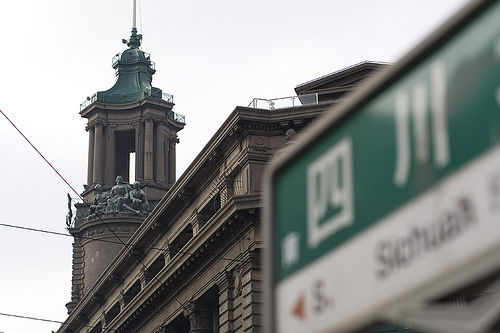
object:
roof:
[77, 0, 177, 112]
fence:
[243, 91, 323, 110]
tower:
[66, 0, 186, 317]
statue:
[120, 27, 143, 47]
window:
[89, 319, 101, 330]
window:
[123, 278, 143, 310]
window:
[145, 250, 165, 282]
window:
[168, 222, 194, 264]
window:
[113, 127, 140, 184]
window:
[189, 285, 225, 330]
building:
[55, 0, 500, 333]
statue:
[84, 172, 155, 218]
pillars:
[91, 126, 107, 182]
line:
[1, 222, 264, 264]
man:
[87, 182, 112, 214]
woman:
[125, 181, 150, 213]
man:
[108, 173, 133, 211]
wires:
[0, 311, 152, 333]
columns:
[134, 112, 175, 181]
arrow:
[284, 288, 309, 322]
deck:
[63, 175, 147, 243]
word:
[358, 188, 472, 283]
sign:
[258, 0, 499, 333]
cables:
[0, 108, 215, 333]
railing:
[242, 91, 346, 109]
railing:
[77, 90, 186, 126]